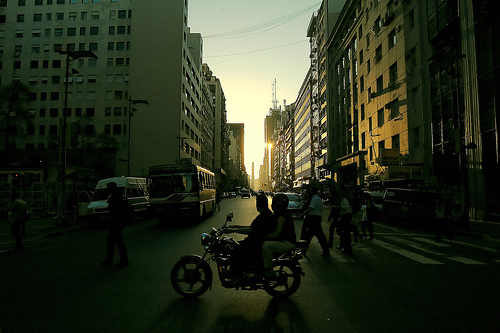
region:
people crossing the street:
[289, 169, 404, 265]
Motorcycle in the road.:
[166, 230, 317, 309]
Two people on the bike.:
[239, 194, 306, 257]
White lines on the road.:
[378, 224, 479, 282]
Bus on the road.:
[132, 152, 238, 232]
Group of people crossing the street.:
[296, 172, 378, 267]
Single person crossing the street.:
[95, 171, 138, 269]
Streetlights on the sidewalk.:
[48, 37, 82, 221]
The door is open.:
[61, 180, 96, 217]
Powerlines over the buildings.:
[180, 0, 345, 67]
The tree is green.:
[1, 80, 43, 153]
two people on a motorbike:
[164, 184, 311, 306]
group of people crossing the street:
[290, 173, 375, 258]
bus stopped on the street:
[136, 159, 221, 219]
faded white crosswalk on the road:
[308, 229, 475, 272]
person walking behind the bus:
[210, 180, 225, 209]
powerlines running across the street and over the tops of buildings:
[196, 6, 358, 64]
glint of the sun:
[266, 140, 278, 150]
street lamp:
[42, 40, 92, 212]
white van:
[81, 172, 150, 219]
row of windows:
[41, 23, 143, 38]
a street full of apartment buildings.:
[270, 0, 490, 177]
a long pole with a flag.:
[50, 25, 95, 175]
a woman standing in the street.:
[425, 185, 450, 250]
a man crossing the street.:
[0, 170, 35, 260]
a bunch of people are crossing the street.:
[295, 165, 385, 255]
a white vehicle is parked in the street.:
[275, 185, 305, 205]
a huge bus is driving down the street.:
[140, 140, 215, 225]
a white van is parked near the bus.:
[85, 165, 150, 215]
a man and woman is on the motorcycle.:
[165, 185, 320, 300]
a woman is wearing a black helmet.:
[265, 186, 286, 211]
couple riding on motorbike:
[178, 200, 340, 327]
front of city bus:
[145, 162, 211, 219]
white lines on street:
[371, 231, 453, 298]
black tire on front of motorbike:
[168, 230, 207, 302]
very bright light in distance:
[243, 129, 271, 187]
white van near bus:
[97, 164, 160, 229]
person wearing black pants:
[306, 181, 334, 265]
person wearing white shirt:
[302, 185, 332, 233]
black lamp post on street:
[63, 45, 85, 183]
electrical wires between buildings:
[197, 14, 329, 70]